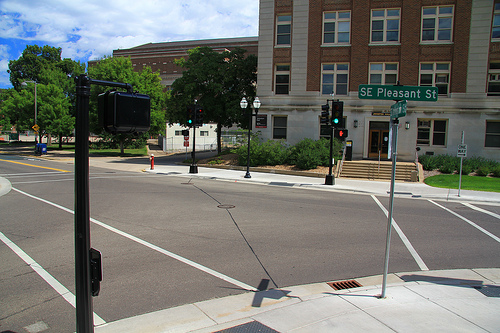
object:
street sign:
[358, 83, 438, 101]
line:
[0, 232, 106, 324]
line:
[13, 187, 258, 291]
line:
[370, 195, 429, 271]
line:
[427, 200, 499, 241]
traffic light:
[332, 118, 340, 125]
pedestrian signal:
[334, 128, 348, 140]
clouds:
[0, 0, 257, 36]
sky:
[1, 0, 260, 90]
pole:
[72, 74, 102, 332]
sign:
[32, 123, 41, 132]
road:
[1, 151, 498, 333]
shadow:
[399, 274, 499, 298]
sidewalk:
[94, 268, 499, 331]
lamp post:
[243, 109, 252, 178]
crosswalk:
[1, 183, 257, 323]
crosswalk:
[373, 195, 499, 275]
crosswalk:
[1, 171, 143, 183]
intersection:
[0, 154, 499, 332]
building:
[247, 0, 499, 171]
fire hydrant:
[148, 153, 156, 170]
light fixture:
[329, 99, 345, 127]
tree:
[165, 75, 220, 163]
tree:
[87, 53, 172, 153]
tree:
[1, 80, 73, 144]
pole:
[379, 119, 398, 297]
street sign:
[389, 99, 408, 119]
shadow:
[216, 277, 303, 307]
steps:
[338, 160, 419, 182]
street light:
[238, 91, 262, 178]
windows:
[320, 9, 352, 48]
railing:
[334, 147, 346, 178]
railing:
[377, 145, 382, 178]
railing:
[412, 151, 421, 182]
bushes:
[229, 130, 346, 170]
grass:
[422, 174, 498, 193]